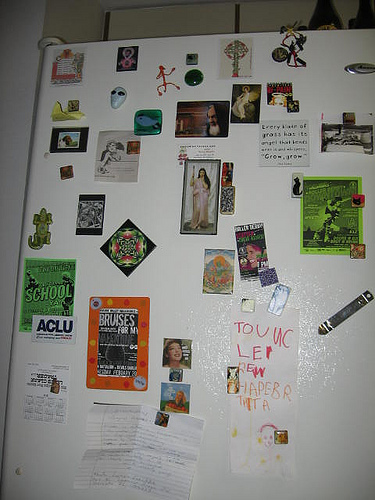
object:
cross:
[218, 33, 254, 80]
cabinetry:
[42, 0, 372, 38]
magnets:
[0, 35, 373, 437]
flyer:
[312, 192, 352, 242]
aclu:
[36, 316, 74, 334]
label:
[344, 61, 372, 78]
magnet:
[132, 107, 163, 137]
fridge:
[0, 35, 373, 497]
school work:
[77, 404, 204, 499]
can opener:
[317, 288, 374, 336]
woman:
[189, 163, 211, 229]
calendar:
[21, 361, 69, 427]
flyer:
[300, 175, 365, 257]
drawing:
[225, 305, 297, 474]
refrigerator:
[0, 24, 374, 493]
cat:
[291, 177, 303, 197]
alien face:
[109, 84, 129, 108]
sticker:
[31, 315, 78, 345]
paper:
[71, 403, 204, 498]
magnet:
[349, 242, 368, 258]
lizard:
[27, 208, 54, 251]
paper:
[93, 128, 142, 183]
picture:
[161, 336, 194, 370]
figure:
[285, 37, 299, 70]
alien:
[110, 85, 128, 109]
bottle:
[307, 0, 343, 30]